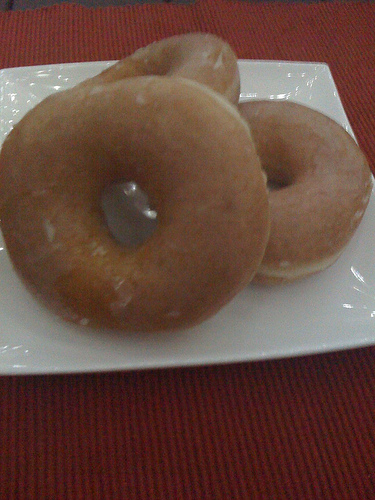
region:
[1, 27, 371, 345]
three doughnuts on a plate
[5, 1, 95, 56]
threaded red table mat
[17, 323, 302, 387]
white plate with doughnuts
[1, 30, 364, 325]
three stacked glazed doughnuts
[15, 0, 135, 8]
gray table under red mat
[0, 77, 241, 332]
one doughnut sitting upright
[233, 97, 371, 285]
one doughnut laying flat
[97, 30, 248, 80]
doughnut laying between two other doughnuts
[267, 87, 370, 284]
glazed doughnut on edge of white plate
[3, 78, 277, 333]
glazed doughnut on the center of white plate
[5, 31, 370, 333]
Three donuts are on the plate.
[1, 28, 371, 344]
The donuts are light brown.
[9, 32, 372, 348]
The donuts are round.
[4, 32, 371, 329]
The donuts are glazed.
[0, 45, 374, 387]
The plate is white.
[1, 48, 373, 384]
The plate is square.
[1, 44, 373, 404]
The plate is made of glass.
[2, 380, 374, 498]
The table is red.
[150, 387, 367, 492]
The table has lines on it.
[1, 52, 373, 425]
The plate is sitting on a table.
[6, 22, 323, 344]
doughnuts on a glazed plate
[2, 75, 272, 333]
hole in middle of brown doughnut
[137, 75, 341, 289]
yellow edges on middle of doughnuts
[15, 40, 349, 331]
doughnuts touching each other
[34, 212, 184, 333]
white markings on top of doughnut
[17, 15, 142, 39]
black and red stripe on cloth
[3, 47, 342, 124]
light shining on white plate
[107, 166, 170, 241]
two shapes of light through doughnut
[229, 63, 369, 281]
doughnut laying flat on plate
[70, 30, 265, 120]
doughnut angled on plate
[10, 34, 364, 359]
Three donuts.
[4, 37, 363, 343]
The donuts have glaze on them.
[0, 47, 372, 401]
The donuts are on a plate.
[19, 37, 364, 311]
Three donuts on white plate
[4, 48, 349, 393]
Square white plate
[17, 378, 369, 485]
Wripples in red cloth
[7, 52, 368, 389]
White plate on red cloth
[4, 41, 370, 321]
Three stacked donuts on plate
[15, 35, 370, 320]
Three donuts with glaze on them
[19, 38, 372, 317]
Three glazed donuts on plate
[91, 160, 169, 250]
Hole in center of donut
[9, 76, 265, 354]
One donut fully faces camera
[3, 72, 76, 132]
Reflection of lights on plate